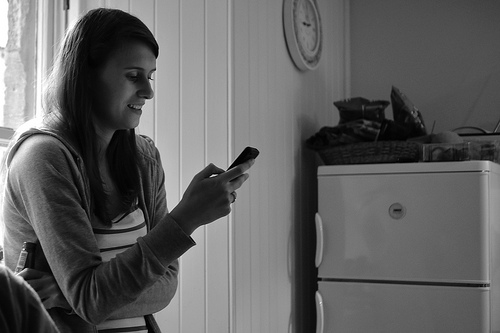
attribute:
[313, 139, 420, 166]
basket — straw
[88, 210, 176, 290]
shirt — striped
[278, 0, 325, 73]
clock — white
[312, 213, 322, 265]
handle — white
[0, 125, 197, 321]
sweat shirt — light grey, hooded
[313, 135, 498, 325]
refrigerator — white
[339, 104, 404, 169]
goodies — packed